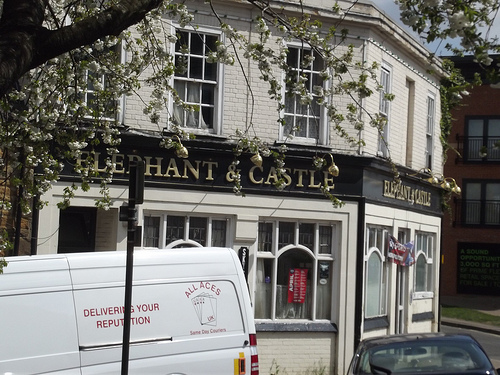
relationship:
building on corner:
[19, 31, 439, 311] [278, 306, 486, 369]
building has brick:
[19, 31, 439, 311] [226, 93, 243, 118]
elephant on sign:
[74, 144, 225, 185] [46, 123, 365, 206]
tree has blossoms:
[0, 5, 163, 112] [92, 63, 114, 94]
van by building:
[6, 250, 263, 370] [19, 31, 439, 311]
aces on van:
[199, 279, 221, 298] [6, 250, 263, 370]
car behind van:
[348, 325, 479, 374] [6, 250, 263, 370]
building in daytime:
[19, 31, 439, 311] [394, 2, 447, 53]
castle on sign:
[249, 159, 341, 195] [46, 123, 365, 206]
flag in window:
[379, 227, 421, 272] [376, 220, 433, 308]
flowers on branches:
[162, 134, 195, 157] [124, 75, 171, 135]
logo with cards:
[181, 276, 232, 343] [188, 295, 221, 326]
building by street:
[445, 63, 497, 308] [428, 312, 499, 366]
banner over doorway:
[361, 226, 445, 271] [392, 264, 408, 339]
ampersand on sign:
[226, 162, 239, 184] [46, 123, 365, 206]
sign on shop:
[46, 123, 365, 206] [79, 193, 383, 352]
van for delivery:
[6, 250, 263, 370] [82, 304, 136, 317]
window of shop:
[376, 220, 433, 308] [79, 193, 383, 352]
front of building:
[366, 14, 443, 289] [19, 31, 439, 311]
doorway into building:
[392, 264, 408, 339] [19, 31, 439, 311]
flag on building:
[379, 227, 421, 272] [19, 31, 439, 311]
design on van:
[159, 276, 243, 346] [6, 250, 263, 370]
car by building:
[348, 325, 479, 374] [19, 31, 439, 311]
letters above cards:
[179, 276, 223, 299] [188, 295, 221, 326]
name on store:
[239, 242, 249, 281] [79, 193, 383, 352]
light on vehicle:
[246, 331, 263, 374] [6, 250, 263, 370]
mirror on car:
[404, 341, 429, 360] [348, 325, 479, 374]